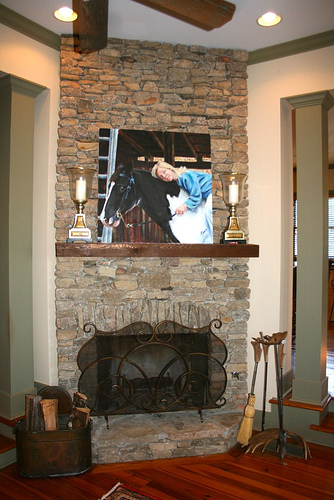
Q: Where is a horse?
A: In picture.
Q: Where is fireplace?
A: In a corner.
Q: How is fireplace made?
A: With stone.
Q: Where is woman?
A: In picture with horse.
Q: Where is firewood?
A: Metal container on left.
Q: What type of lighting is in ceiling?
A: Recessed lighting.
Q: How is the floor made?
A: Out of wood.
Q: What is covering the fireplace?
A: Decorative fireplace screen.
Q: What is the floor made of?
A: Wood.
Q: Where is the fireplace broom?
A: Right of fireplace.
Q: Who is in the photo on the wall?
A: Girl and a horse.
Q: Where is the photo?
A: On the mantle.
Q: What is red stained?
A: Wood floor.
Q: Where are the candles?
A: On the mantel.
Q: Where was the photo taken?
A: In a home.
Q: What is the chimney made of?
A: Stones.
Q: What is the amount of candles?
A: Two.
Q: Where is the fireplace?
A: In the room.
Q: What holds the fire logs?
A: A container.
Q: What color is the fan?
A: Brown and black.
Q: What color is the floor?
A: Brown.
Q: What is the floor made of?
A: Wood.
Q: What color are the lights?
A: Yellow.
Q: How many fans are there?
A: One.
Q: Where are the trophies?
A: On the mantle.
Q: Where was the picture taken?
A: In a living room.